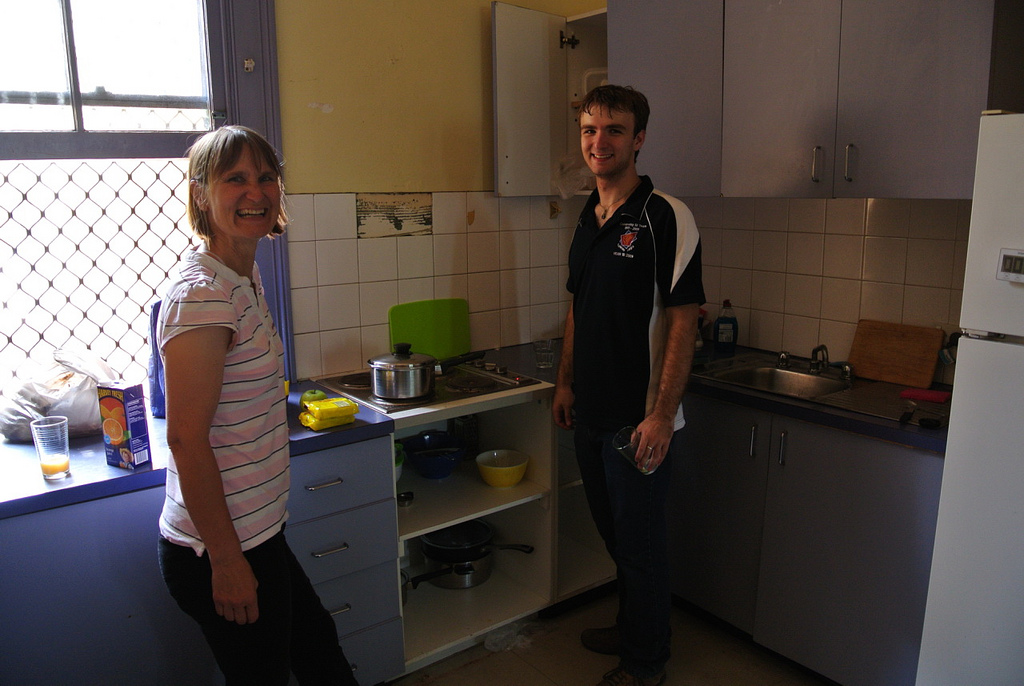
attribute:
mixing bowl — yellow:
[449, 421, 534, 519]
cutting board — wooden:
[808, 269, 945, 490]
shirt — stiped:
[199, 371, 260, 557]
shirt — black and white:
[588, 274, 664, 406]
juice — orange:
[39, 468, 53, 482]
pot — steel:
[344, 342, 437, 435]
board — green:
[241, 297, 540, 364]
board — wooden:
[856, 320, 904, 375]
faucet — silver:
[770, 314, 833, 475]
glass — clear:
[619, 437, 697, 464]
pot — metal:
[413, 446, 496, 518]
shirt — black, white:
[563, 173, 710, 437]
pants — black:
[153, 529, 296, 686]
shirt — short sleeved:
[233, 364, 272, 565]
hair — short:
[149, 207, 195, 236]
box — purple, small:
[92, 374, 155, 470]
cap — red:
[716, 294, 736, 308]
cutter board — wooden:
[844, 310, 942, 384]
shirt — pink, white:
[155, 243, 298, 553]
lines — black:
[228, 320, 278, 373]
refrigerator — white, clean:
[913, 106, 1019, 679]